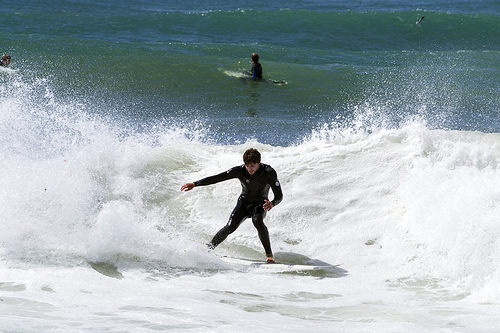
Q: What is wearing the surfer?
A: A black wetsuit.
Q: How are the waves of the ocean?
A: Choppy.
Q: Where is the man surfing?
A: In the ocean.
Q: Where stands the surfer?
A: On a surfboard.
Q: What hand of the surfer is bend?
A: Left hand.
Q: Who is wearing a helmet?
A: A man.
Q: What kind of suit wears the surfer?
A: A wet suit.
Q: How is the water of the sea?
A: Foamy.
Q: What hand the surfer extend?
A: Right hand.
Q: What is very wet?
A: Water.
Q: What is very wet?
A: The man.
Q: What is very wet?
A: The man.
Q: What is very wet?
A: The man.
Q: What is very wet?
A: Water.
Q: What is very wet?
A: Water.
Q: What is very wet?
A: The man.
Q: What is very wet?
A: The man.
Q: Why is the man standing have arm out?
A: Balance.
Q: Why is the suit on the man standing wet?
A: In the water.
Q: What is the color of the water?
A: Green.